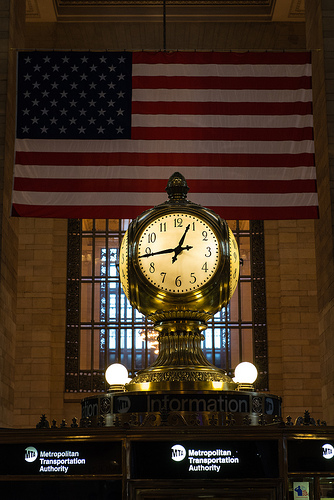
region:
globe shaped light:
[104, 363, 129, 394]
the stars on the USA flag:
[13, 47, 134, 140]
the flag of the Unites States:
[13, 46, 322, 221]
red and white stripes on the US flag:
[158, 51, 238, 142]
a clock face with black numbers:
[140, 213, 220, 292]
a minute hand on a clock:
[140, 245, 195, 260]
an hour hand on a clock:
[170, 222, 191, 263]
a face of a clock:
[228, 225, 241, 298]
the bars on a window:
[88, 258, 123, 337]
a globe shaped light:
[228, 356, 267, 395]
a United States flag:
[12, 48, 321, 222]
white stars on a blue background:
[21, 56, 126, 136]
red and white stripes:
[136, 61, 303, 211]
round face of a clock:
[134, 213, 221, 297]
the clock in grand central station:
[79, 168, 274, 421]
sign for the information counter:
[81, 387, 275, 422]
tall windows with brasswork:
[69, 216, 268, 390]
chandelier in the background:
[134, 321, 163, 354]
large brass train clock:
[108, 170, 244, 390]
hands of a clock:
[133, 223, 197, 258]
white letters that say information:
[135, 394, 251, 414]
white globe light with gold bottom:
[226, 359, 264, 399]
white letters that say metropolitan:
[37, 446, 81, 459]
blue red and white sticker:
[294, 475, 306, 496]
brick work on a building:
[274, 315, 327, 412]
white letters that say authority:
[185, 464, 226, 474]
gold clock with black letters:
[89, 203, 230, 381]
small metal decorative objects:
[27, 412, 89, 451]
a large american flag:
[20, 64, 331, 235]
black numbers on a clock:
[124, 221, 209, 286]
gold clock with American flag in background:
[7, 43, 324, 367]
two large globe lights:
[104, 352, 258, 394]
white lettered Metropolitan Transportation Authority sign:
[167, 442, 241, 474]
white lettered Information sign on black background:
[142, 393, 249, 414]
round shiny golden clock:
[127, 202, 227, 306]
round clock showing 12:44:
[129, 202, 226, 306]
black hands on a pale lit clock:
[135, 211, 196, 266]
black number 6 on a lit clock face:
[172, 272, 184, 288]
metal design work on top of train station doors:
[32, 411, 331, 431]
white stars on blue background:
[13, 48, 132, 140]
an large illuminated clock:
[108, 168, 245, 391]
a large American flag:
[7, 44, 324, 221]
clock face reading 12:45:
[139, 207, 218, 293]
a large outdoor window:
[95, 246, 231, 366]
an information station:
[14, 170, 331, 497]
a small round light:
[99, 357, 126, 390]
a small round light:
[231, 357, 258, 391]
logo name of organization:
[166, 441, 240, 476]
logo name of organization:
[17, 442, 90, 473]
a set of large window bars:
[65, 215, 265, 389]